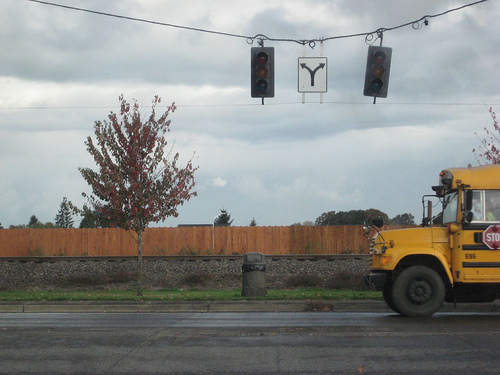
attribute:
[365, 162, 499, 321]
bus — yellow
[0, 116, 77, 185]
clouds — white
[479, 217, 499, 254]
sign — white, red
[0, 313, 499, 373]
street — asphalt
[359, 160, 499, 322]
school bus — yellow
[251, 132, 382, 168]
clouds — white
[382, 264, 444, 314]
tire — rubber, black, round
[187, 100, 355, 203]
clouds — white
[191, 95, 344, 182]
sky — blue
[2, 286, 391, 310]
grass — green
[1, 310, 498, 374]
road — semi wet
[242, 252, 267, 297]
trash can — gray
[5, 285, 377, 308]
grass — short, green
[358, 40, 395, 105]
traffic light — above, hanging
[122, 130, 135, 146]
leaves — red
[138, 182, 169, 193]
leaves — red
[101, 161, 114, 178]
leaves — red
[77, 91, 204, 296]
tree — small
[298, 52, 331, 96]
sign — square, white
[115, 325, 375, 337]
dirt — laying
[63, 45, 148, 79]
cloud — white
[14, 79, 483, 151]
clouds — white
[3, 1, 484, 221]
sky — blue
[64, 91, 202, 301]
maple tree — red